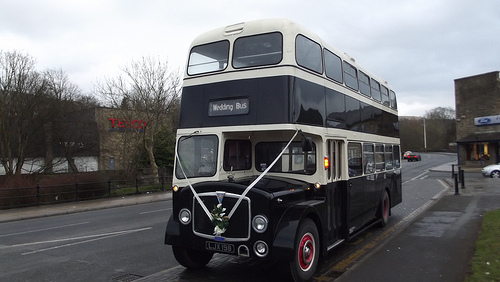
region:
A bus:
[194, 31, 282, 280]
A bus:
[213, 61, 345, 268]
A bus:
[207, 105, 322, 225]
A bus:
[201, 76, 223, 119]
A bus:
[238, 158, 298, 255]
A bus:
[244, 129, 275, 188]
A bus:
[256, 100, 262, 110]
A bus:
[258, 210, 313, 279]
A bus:
[265, 139, 335, 276]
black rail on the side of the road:
[426, 156, 485, 201]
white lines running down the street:
[25, 229, 144, 252]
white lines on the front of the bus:
[170, 124, 306, 217]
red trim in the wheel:
[290, 230, 322, 269]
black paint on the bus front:
[203, 177, 366, 217]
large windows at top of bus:
[185, 25, 302, 84]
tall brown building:
[433, 66, 495, 151]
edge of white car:
[463, 154, 493, 184]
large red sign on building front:
[100, 112, 161, 133]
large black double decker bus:
[160, 26, 418, 243]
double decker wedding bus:
[158, 11, 407, 278]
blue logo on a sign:
[474, 116, 494, 125]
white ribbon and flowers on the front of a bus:
[174, 130, 306, 235]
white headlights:
[253, 215, 270, 232]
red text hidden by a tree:
[102, 111, 160, 128]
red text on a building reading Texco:
[101, 114, 156, 129]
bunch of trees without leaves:
[1, 47, 182, 218]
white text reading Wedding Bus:
[206, 100, 251, 115]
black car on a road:
[404, 148, 420, 164]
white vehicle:
[481, 153, 499, 176]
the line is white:
[87, 228, 102, 255]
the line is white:
[94, 218, 106, 238]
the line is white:
[83, 222, 108, 242]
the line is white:
[41, 223, 73, 254]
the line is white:
[84, 231, 104, 238]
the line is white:
[90, 234, 105, 242]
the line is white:
[67, 236, 93, 245]